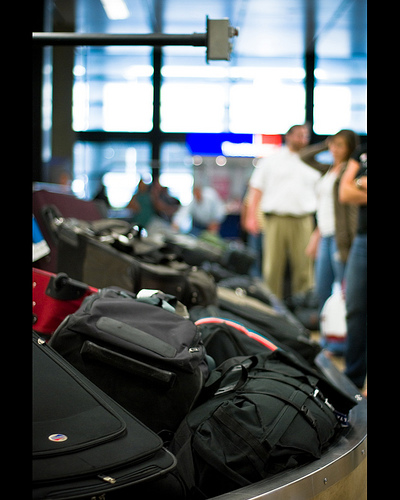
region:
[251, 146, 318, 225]
Man is wearing a shirt.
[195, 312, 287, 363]
Stripe on a bag.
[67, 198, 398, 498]
The bags are on a moving rack.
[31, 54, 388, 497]
Was taken in an airport.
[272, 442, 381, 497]
The rack is silver.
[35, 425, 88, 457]
Decal on the suitcase.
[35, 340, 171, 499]
The suitcase is black.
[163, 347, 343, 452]
The bag is black.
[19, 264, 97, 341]
The suitcase is red.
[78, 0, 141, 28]
Light on the ceiling.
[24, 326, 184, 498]
black suitcase on rolling mat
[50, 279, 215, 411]
black suitcase on rolling mat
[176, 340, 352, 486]
black suitcase on rolling mat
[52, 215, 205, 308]
black suitcase on rolling mat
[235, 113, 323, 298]
man wearing white shirt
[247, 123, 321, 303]
man wearing kaki pants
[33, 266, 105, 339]
red luggage with wheels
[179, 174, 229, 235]
man wearing white shirt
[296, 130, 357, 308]
woman wearing blue pair of jeans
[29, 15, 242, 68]
button attached to horizontal pole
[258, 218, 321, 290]
The pants are tan.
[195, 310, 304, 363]
Stripe on the bag.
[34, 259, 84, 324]
The suitcase is red.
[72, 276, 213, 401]
Backpack on luggage.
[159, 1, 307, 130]
Light coming through the windows.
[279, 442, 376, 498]
The side is silver.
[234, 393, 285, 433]
the black luggage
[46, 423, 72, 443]
a button on the luggage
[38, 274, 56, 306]
the red luggage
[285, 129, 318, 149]
the man's head in the background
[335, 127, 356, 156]
the woman's head in the background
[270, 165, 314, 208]
the man's white shirt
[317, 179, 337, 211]
the woman's white shirt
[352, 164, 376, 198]
the persons watch in the backgroun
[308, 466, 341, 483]
the metal belt for the luggage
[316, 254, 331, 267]
the woman's blue jeans in the background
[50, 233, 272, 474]
luggage on return conveyor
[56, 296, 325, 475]
luggage on conveyor is black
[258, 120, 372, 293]
people in background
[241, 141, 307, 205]
man wears white shirt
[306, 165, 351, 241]
woman wears white shirt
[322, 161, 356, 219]
woman wears brown shirt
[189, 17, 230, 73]
grey camera over conveyor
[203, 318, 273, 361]
red white and blue tag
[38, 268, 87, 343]
red and black luggage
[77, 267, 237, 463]
rectangular black luggage